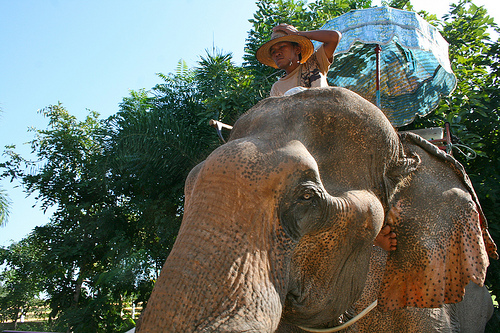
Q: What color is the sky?
A: Blue.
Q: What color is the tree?
A: Green.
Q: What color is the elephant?
A: Gray.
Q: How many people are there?
A: One.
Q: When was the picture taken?
A: Daytime.